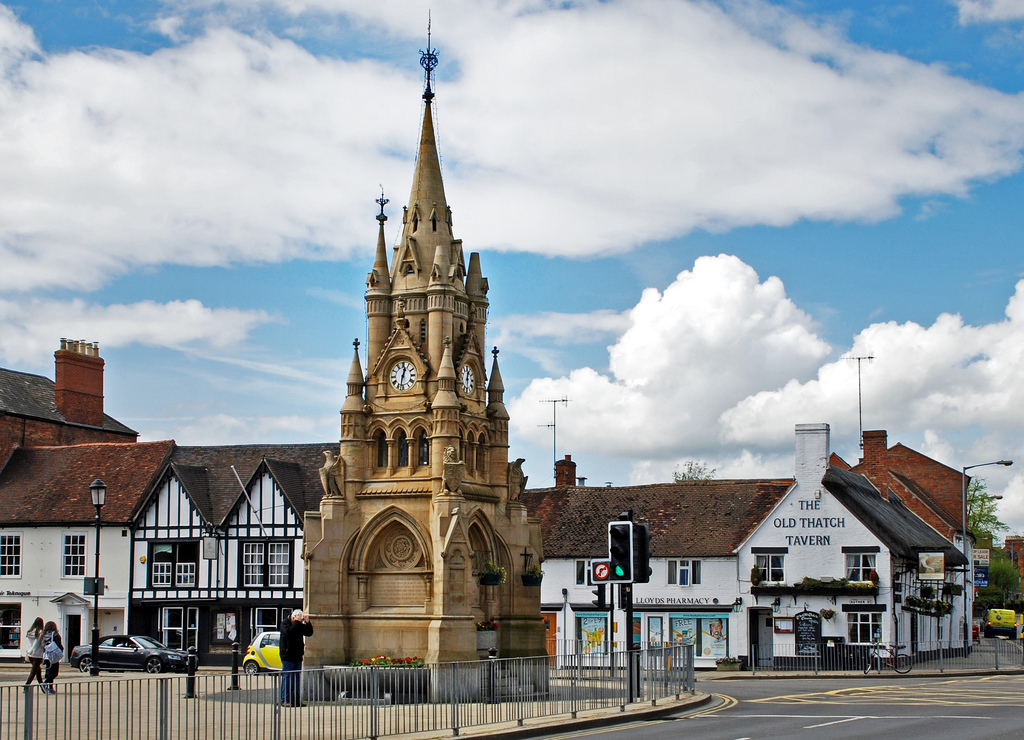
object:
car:
[69, 634, 200, 674]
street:
[0, 608, 1022, 736]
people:
[30, 574, 73, 651]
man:
[279, 608, 314, 707]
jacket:
[276, 619, 312, 659]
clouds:
[0, 0, 1024, 543]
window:
[61, 529, 89, 578]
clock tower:
[297, 114, 548, 740]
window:
[0, 531, 22, 580]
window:
[147, 537, 179, 587]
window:
[176, 538, 196, 586]